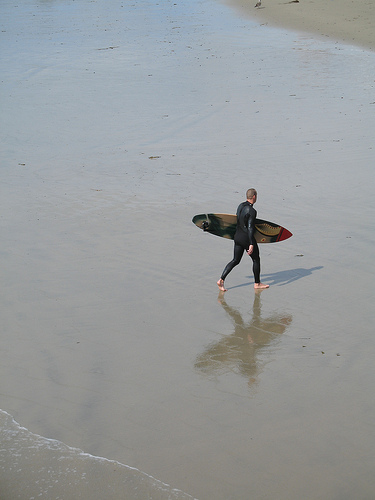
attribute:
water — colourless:
[187, 98, 306, 174]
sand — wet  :
[46, 81, 366, 475]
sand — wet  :
[44, 67, 374, 498]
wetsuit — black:
[214, 186, 286, 304]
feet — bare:
[206, 267, 277, 299]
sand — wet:
[10, 10, 183, 492]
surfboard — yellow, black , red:
[183, 205, 299, 245]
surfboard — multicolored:
[189, 209, 291, 245]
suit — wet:
[222, 200, 264, 283]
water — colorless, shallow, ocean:
[3, 409, 191, 498]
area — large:
[6, 3, 363, 486]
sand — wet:
[14, 13, 363, 481]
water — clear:
[216, 323, 300, 400]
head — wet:
[238, 184, 265, 196]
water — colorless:
[96, 376, 325, 495]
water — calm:
[4, 3, 369, 494]